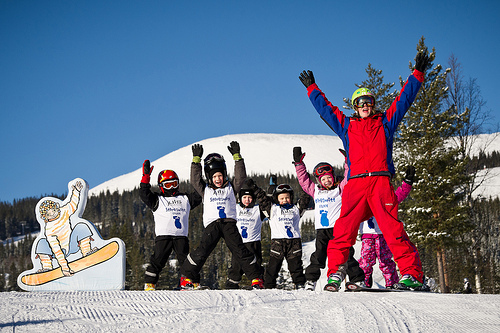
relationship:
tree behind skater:
[382, 40, 489, 265] [304, 65, 442, 302]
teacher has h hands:
[292, 28, 444, 297] [284, 40, 455, 107]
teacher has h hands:
[292, 28, 444, 297] [134, 135, 358, 186]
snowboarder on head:
[345, 282, 432, 292] [349, 86, 378, 117]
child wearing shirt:
[137, 158, 205, 291] [201, 180, 239, 223]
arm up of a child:
[381, 65, 434, 136] [189, 133, 251, 288]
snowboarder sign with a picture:
[16, 175, 128, 292] [17, 177, 118, 285]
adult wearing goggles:
[295, 36, 440, 290] [356, 94, 373, 106]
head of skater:
[347, 80, 382, 120] [294, 60, 439, 310]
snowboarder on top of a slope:
[293, 46, 438, 294] [0, 289, 494, 331]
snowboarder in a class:
[345, 282, 432, 292] [128, 120, 420, 288]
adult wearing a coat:
[297, 48, 429, 289] [305, 69, 428, 181]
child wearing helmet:
[137, 158, 205, 291] [344, 82, 380, 109]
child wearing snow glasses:
[137, 158, 205, 291] [159, 178, 179, 190]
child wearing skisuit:
[302, 79, 422, 194] [304, 72, 426, 279]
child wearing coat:
[282, 140, 364, 298] [292, 150, 353, 246]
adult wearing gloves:
[297, 48, 429, 289] [293, 45, 433, 85]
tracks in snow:
[176, 275, 478, 322] [83, 291, 498, 330]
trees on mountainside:
[5, 153, 498, 239] [0, 273, 491, 329]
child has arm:
[137, 158, 205, 291] [125, 152, 173, 210]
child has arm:
[178, 139, 266, 290] [188, 157, 202, 194]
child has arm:
[262, 170, 311, 288] [297, 190, 311, 213]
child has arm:
[125, 154, 206, 299] [294, 57, 350, 144]